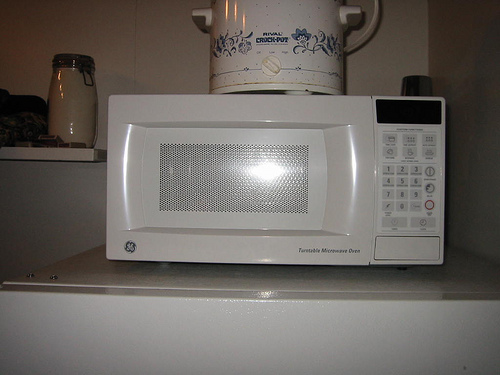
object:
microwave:
[104, 91, 447, 268]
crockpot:
[189, 2, 383, 96]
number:
[396, 165, 408, 173]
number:
[410, 166, 421, 174]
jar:
[46, 53, 99, 148]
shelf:
[1, 143, 96, 164]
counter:
[1, 142, 98, 163]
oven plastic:
[264, 214, 304, 228]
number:
[387, 177, 391, 183]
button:
[396, 177, 408, 185]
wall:
[0, 0, 500, 152]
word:
[256, 31, 291, 45]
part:
[458, 186, 493, 209]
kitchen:
[0, 0, 499, 375]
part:
[228, 330, 265, 351]